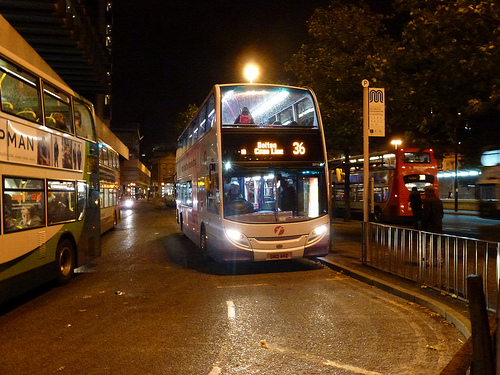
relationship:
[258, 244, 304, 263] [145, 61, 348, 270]
license plate on bus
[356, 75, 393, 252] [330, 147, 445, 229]
sign by bus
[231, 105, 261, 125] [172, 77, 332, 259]
person on bus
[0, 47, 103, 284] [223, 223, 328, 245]
bus has headlights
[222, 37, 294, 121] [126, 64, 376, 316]
street light behind bus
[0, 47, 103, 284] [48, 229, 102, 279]
bus has tires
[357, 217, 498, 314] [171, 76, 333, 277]
railing beside bus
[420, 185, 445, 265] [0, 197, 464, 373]
people on street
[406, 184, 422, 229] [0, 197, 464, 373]
people on street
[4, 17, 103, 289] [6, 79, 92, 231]
bus with passengers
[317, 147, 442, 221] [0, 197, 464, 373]
bus on street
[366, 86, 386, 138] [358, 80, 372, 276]
sign on pole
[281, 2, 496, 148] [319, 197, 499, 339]
trees on sidewalk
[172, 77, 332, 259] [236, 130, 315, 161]
bus next to destiantion